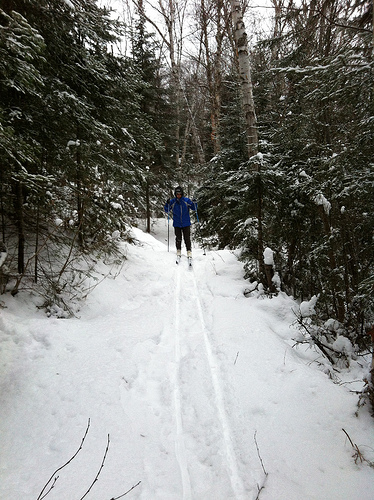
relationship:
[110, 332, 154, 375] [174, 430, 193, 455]
tracks in snow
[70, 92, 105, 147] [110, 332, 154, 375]
tree by tracks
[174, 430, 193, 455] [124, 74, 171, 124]
snow on trees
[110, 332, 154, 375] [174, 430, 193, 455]
tracks are on snow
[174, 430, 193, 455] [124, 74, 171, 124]
snow in trees